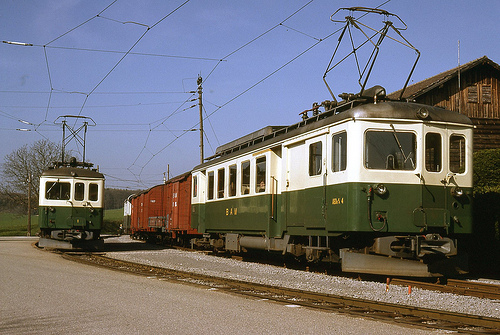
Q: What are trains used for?
A: Moving cargo and people.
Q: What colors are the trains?
A: Green, White.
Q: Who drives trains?
A: Conductors.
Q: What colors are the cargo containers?
A: Red.